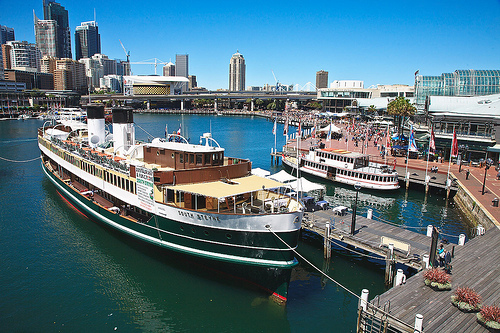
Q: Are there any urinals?
A: No, there are no urinals.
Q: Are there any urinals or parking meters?
A: No, there are no urinals or parking meters.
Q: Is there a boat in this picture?
A: Yes, there is a boat.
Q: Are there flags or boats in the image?
A: Yes, there is a boat.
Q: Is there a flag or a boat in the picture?
A: Yes, there is a boat.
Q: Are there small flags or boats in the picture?
A: Yes, there is a small boat.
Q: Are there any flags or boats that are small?
A: Yes, the boat is small.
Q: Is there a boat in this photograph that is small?
A: Yes, there is a small boat.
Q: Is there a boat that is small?
A: Yes, there is a boat that is small.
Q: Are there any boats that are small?
A: Yes, there is a boat that is small.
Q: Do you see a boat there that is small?
A: Yes, there is a boat that is small.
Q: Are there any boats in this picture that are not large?
A: Yes, there is a small boat.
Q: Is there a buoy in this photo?
A: No, there are no buoys.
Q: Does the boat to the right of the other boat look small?
A: Yes, the boat is small.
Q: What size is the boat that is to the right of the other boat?
A: The boat is small.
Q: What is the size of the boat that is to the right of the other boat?
A: The boat is small.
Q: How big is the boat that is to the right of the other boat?
A: The boat is small.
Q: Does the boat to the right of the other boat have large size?
A: No, the boat is small.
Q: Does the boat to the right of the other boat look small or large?
A: The boat is small.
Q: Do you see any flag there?
A: Yes, there is a flag.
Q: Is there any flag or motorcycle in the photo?
A: Yes, there is a flag.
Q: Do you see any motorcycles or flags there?
A: Yes, there is a flag.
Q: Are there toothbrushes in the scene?
A: No, there are no toothbrushes.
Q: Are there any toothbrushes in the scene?
A: No, there are no toothbrushes.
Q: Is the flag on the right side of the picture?
A: Yes, the flag is on the right of the image.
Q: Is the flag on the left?
A: No, the flag is on the right of the image.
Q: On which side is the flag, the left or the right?
A: The flag is on the right of the image.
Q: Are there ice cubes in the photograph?
A: No, there are no ice cubes.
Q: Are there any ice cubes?
A: No, there are no ice cubes.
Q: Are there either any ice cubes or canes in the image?
A: No, there are no ice cubes or canes.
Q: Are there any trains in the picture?
A: Yes, there is a train.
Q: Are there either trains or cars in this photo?
A: Yes, there is a train.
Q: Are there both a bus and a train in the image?
A: No, there is a train but no buses.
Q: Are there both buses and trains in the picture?
A: No, there is a train but no buses.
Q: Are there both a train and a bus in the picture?
A: No, there is a train but no buses.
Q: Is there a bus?
A: No, there are no buses.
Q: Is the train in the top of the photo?
A: Yes, the train is in the top of the image.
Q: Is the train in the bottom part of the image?
A: No, the train is in the top of the image.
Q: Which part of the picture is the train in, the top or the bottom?
A: The train is in the top of the image.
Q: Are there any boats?
A: Yes, there is a boat.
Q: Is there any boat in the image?
A: Yes, there is a boat.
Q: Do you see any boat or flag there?
A: Yes, there is a boat.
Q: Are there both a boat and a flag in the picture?
A: Yes, there are both a boat and a flag.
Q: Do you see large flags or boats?
A: Yes, there is a large boat.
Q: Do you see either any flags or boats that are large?
A: Yes, the boat is large.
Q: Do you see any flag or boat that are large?
A: Yes, the boat is large.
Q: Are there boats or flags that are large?
A: Yes, the boat is large.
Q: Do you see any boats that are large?
A: Yes, there is a large boat.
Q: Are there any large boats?
A: Yes, there is a large boat.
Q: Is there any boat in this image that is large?
A: Yes, there is a boat that is large.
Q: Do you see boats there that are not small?
A: Yes, there is a large boat.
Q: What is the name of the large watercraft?
A: The watercraft is a boat.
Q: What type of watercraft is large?
A: The watercraft is a boat.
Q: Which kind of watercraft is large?
A: The watercraft is a boat.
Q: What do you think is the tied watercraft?
A: The watercraft is a boat.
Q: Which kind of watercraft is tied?
A: The watercraft is a boat.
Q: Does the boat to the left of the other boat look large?
A: Yes, the boat is large.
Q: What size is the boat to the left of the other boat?
A: The boat is large.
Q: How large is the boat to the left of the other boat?
A: The boat is large.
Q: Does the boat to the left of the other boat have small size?
A: No, the boat is large.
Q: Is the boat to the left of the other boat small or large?
A: The boat is large.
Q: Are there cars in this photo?
A: No, there are no cars.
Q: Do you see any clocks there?
A: No, there are no clocks.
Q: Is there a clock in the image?
A: No, there are no clocks.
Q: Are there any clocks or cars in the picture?
A: No, there are no clocks or cars.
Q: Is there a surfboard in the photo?
A: No, there are no surfboards.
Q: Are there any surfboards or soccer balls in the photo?
A: No, there are no surfboards or soccer balls.